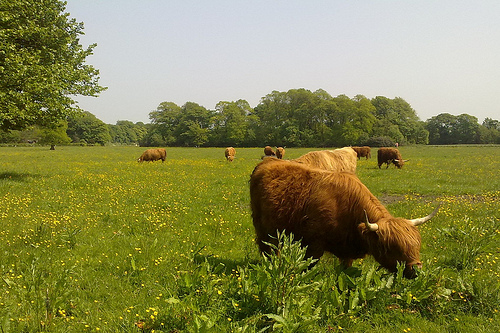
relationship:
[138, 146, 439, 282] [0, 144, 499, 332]
group in field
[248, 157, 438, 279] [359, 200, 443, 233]
animal has horns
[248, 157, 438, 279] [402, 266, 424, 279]
animal has nose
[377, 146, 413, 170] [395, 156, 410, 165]
cow has horns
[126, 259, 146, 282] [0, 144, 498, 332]
weed in field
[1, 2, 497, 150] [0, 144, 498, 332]
trees around field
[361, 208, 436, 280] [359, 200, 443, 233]
head has horns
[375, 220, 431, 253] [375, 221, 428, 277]
hair covers face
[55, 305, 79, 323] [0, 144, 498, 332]
flower in field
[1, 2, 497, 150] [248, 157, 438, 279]
trees behind animal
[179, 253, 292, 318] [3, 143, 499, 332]
shadow in grass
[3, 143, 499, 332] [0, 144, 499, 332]
grass on field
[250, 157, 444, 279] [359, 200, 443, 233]
animal has horns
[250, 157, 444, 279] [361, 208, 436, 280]
animal has head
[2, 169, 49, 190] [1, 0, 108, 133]
shadow near tree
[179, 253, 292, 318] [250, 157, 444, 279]
shadow near animal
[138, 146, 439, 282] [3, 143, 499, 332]
group on grass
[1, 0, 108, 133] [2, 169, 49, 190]
tree has shadow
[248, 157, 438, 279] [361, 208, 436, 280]
animal has head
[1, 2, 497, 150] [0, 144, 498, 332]
trees in field